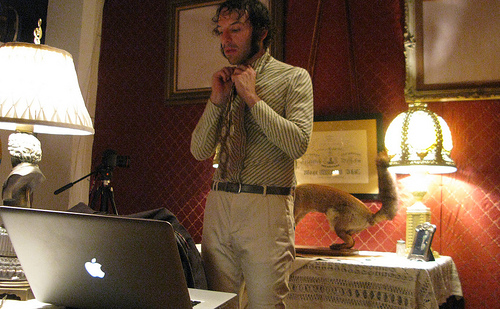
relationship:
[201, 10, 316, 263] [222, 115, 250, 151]
man wearing tie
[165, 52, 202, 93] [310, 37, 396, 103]
photo on wall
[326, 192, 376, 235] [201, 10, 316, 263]
cat near man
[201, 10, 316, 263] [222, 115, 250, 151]
man with tie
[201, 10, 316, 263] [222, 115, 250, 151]
man using tie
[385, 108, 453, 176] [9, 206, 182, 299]
lamp near laptop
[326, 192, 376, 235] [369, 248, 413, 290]
cat on table cloth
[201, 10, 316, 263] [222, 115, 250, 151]
man trying tie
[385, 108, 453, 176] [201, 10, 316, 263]
lamp near man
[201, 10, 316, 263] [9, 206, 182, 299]
man near laptop